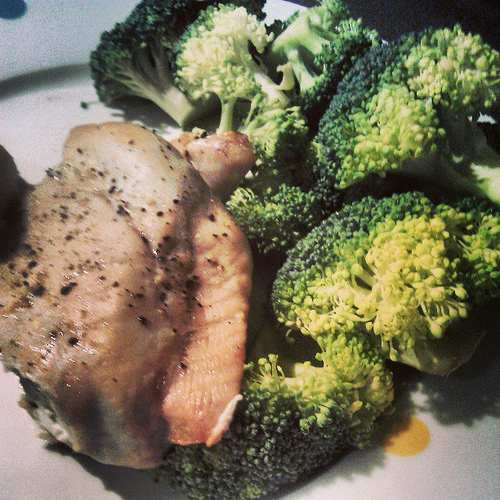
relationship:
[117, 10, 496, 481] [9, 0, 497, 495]
broccoli on plate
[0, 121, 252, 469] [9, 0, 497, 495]
beef on plate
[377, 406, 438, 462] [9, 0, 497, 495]
grease on plate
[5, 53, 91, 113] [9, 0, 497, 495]
dip in plate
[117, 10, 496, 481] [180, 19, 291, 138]
broccoli has part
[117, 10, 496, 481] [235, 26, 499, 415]
broccoli has part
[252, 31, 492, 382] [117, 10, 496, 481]
light green on broccoli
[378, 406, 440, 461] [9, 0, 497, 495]
dot on plate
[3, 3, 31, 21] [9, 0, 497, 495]
dot on plate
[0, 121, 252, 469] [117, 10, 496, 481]
beef next to broccoli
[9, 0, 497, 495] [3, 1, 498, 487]
plate with meal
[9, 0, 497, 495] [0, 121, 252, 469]
plate with beef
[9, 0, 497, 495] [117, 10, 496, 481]
plate with broccoli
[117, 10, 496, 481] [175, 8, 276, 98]
broccoli has piece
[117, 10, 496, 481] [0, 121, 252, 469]
broccoli with beef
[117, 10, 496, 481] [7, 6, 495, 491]
broccoli on dish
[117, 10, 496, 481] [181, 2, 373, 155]
broccoli has florets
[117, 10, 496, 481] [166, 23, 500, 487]
broccoli has florets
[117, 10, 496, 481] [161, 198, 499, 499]
broccoli has florets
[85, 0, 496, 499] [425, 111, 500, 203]
broccoli has stem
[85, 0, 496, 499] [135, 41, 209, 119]
broccoli has stem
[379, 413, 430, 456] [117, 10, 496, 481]
dot under broccoli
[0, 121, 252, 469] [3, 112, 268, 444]
beef over beef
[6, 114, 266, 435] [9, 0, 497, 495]
pork on plate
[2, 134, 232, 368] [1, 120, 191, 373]
seasoning on crust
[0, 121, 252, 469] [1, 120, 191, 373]
beef has crust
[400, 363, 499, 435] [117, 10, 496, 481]
shadow from broccoli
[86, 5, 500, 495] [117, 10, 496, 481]
colors on broccoli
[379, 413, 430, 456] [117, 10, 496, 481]
dot on broccoli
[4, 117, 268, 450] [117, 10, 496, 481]
chicken on top of broccoli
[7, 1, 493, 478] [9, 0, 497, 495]
food on plate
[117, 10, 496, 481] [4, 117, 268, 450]
broccoli next to chicken